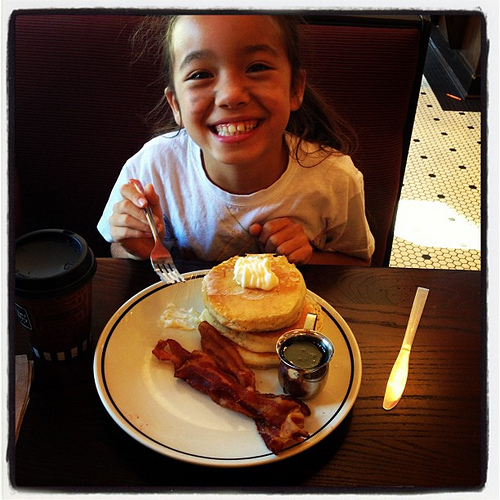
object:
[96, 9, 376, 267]
girl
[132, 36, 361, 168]
brown hair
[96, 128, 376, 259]
shirt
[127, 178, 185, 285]
fork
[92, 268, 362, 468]
plate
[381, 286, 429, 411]
knife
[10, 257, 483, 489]
table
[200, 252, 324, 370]
pancakes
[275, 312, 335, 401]
cup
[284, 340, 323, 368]
syrup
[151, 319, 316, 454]
bacon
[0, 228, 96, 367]
coffee cup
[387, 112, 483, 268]
floor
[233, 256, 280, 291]
butter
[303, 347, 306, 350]
bubbles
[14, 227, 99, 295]
lid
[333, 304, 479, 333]
lines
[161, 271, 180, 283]
cream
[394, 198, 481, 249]
light reflection